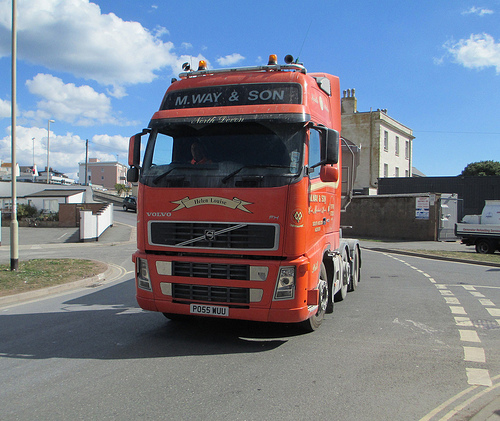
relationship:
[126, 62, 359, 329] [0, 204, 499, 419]
truck on road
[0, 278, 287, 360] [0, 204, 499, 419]
shadow on road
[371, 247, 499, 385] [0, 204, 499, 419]
lines on road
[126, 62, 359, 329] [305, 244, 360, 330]
truck has tires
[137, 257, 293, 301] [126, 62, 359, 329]
headlights on truck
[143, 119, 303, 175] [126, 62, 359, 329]
windshield on truck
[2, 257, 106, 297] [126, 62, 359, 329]
grass beside truck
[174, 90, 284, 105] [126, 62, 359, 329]
words on truck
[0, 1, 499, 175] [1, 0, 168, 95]
sky has clouds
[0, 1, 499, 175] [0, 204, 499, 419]
sky above road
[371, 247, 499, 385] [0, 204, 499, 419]
lines are on road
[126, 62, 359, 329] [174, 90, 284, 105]
truck has words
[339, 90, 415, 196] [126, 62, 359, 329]
building behind truck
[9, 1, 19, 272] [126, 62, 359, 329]
pole beside truck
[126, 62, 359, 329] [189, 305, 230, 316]
truck has a license plate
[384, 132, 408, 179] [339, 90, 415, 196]
windows on building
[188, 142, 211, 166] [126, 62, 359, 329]
man inside truck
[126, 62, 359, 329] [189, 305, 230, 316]
truck has license plate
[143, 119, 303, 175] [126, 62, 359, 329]
windshield of truck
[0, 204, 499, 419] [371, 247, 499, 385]
road has lines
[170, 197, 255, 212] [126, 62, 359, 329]
logo on truck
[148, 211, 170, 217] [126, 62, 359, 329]
volvo on truck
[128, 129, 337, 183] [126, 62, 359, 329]
mirrors on truck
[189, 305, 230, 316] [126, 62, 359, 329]
license plate on truck